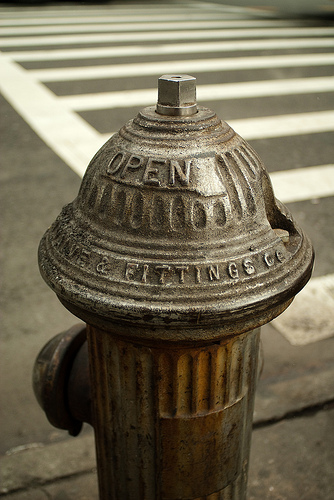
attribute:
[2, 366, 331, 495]
curb — low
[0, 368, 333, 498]
sidewalk — concrete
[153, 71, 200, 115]
bolt — giant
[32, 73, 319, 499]
fire hydrant — dry, grey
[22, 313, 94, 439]
valve — closed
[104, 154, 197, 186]
word — open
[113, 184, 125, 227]
indentation — oval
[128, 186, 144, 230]
indentation — oval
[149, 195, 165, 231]
indentation — oval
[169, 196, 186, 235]
indentation — oval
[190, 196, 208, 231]
indentation — oval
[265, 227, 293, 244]
bolt — small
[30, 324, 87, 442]
rimmed plug — protuding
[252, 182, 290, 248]
opening — deep, arched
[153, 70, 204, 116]
angle bolt — angled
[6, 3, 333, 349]
lines — thick, white, gray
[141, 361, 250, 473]
rust — brown